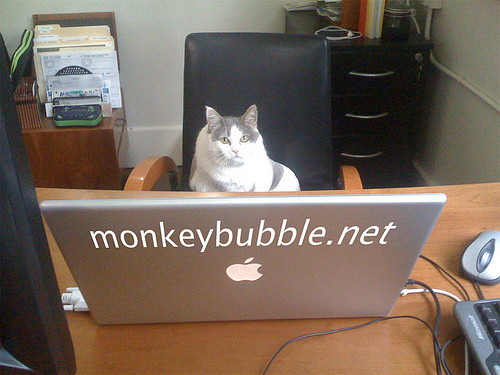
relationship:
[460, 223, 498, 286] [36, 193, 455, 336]
mouse for computer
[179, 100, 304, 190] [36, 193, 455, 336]
cat in front of laptop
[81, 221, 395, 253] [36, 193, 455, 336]
text on computer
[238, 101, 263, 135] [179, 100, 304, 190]
ears of cat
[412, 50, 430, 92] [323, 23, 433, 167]
lock on drawer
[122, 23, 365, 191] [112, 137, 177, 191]
chair has arm rests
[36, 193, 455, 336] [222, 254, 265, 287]
laptop has apple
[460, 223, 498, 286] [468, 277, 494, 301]
mouse has wires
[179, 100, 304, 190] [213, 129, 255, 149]
cat has eyes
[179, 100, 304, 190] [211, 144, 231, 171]
cat has whiskers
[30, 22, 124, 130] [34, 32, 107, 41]
folders have papers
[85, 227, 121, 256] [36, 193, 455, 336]
m on laptop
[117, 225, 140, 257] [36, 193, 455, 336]
o on laptop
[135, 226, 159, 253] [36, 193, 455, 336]
n on laptop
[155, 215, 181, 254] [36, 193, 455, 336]
k on laptop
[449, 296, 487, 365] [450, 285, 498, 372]
edge of keyboard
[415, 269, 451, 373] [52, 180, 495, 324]
wires on desk